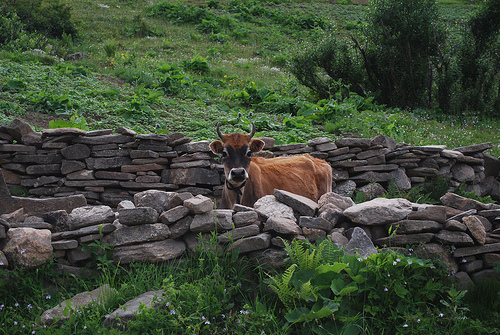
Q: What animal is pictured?
A: Cow.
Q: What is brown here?
A: The cow.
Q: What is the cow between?
A: Rocks.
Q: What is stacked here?
A: Stones.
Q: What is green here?
A: The grass.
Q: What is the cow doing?
A: Standing.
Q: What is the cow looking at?
A: The camera.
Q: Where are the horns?
A: Cows head.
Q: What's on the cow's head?
A: Horns.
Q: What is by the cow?
A: Rocks.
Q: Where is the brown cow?
A: Behind front wall.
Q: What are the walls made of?
A: Gray stones.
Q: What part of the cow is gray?
A: Face.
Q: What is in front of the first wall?
A: Grass and small plants.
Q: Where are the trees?
A: Behind back wall.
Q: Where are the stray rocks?
A: In front of front wall.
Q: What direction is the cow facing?
A: Towards the camera.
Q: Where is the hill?
A: Behind back wall.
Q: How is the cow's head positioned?
A: Looking over left shoulder.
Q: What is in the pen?
A: Cow.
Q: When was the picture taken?
A: Daytime.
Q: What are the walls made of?
A: Rocks.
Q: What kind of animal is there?
A: A bull.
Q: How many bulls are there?
A: One.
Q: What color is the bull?
A: Brown.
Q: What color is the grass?
A: Green.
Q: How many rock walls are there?
A: Two.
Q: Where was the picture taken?
A: At the rock wall.